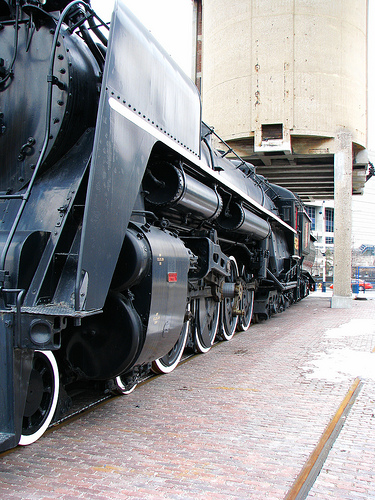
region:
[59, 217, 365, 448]
picture taken outdoors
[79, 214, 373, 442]
picture taken during the day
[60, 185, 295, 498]
the ground is covered with bricks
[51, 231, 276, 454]
a train on the tracks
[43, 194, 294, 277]
the train is black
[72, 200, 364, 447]
the train is at the station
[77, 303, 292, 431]
the train is not moving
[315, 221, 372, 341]
a red car in the background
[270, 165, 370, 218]
a large siloh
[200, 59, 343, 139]
the train is under a large building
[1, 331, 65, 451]
This is a wheel of a train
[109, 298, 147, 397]
This is a wheel of a train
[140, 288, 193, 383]
This is a wheel of a train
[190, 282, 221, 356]
This is a wheel of a train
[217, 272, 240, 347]
This is a wheel of a train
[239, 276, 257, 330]
This is a wheel of a train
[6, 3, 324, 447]
This is a train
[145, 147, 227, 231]
This is an oil tank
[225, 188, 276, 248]
This is an oil tank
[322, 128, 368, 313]
This is a supporting pillar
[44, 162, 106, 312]
steps on the front of the train engine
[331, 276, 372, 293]
red car parked on the street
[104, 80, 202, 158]
a row of rivets in the sheet metal of the engine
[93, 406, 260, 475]
red brick pavement by train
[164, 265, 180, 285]
red sign on side of engine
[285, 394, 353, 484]
one rail of a train track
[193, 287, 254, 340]
wheels on the train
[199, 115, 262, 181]
black metal rail along the train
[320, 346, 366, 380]
dirt on the pavement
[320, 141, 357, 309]
large steel post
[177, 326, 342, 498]
red brick walkway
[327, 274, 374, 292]
a red car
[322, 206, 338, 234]
windows to a building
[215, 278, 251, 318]
a crank on a train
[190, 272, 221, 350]
a wheel on a train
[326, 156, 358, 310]
a concrete support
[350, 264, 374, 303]
a tall blue fence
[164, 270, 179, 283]
a piece of red metal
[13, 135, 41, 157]
a hand grip on the train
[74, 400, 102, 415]
part of a train track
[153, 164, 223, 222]
a tank is on the train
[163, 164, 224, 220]
the tank is black in color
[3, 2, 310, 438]
the train is made of metal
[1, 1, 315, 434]
the train is black in color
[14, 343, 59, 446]
the wheel has a white rim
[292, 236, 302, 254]
numbers are painted on the train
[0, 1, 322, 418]
the train is on display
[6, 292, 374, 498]
the ground is paved with bricks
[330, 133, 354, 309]
a column is besides the train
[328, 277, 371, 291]
a red car is on the distance